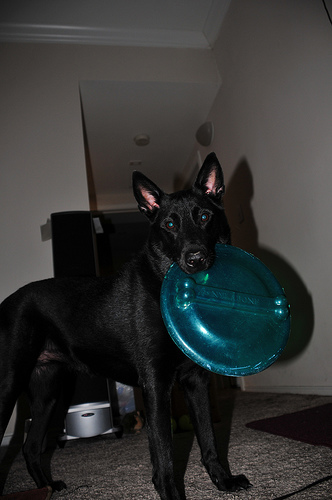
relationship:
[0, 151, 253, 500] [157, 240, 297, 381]
black dog holding frisbee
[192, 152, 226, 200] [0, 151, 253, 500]
dog's ear on black dog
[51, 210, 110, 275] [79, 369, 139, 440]
speaker on shelf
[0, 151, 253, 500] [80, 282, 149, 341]
black dog has black fur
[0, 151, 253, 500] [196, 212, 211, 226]
black dog has an eye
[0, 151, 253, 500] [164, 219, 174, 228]
black dog has an eye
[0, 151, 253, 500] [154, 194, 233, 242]
black dog has eyes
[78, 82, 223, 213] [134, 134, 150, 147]
ceiling has fire alarm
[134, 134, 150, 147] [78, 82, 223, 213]
fire alarm on ceiling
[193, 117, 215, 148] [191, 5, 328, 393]
light on wall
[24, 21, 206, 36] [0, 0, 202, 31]
molding near ceiling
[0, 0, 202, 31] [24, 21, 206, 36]
ceiling has molding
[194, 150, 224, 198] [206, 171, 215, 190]
dog's ear has pink skin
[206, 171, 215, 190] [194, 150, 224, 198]
pink skin in dog's ear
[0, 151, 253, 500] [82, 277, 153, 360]
black dog has black fur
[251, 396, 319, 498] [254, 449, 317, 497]
floor has carpet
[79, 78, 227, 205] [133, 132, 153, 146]
ceiling has fire alarm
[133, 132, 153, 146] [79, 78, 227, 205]
fire alarm on ceiling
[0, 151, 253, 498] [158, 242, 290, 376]
black dog holding frisbee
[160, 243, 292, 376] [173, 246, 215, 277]
frisbee in dog's mouth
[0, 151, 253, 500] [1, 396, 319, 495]
black dog on carpet